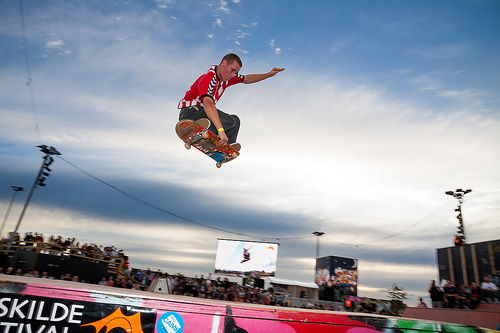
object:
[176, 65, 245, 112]
shirt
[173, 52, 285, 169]
skateboarder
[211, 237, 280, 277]
screen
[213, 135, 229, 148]
hand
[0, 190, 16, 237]
pole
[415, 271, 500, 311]
crowd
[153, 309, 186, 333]
advertisement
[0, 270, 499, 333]
wall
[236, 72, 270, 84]
arm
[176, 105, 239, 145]
pants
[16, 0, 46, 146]
wire